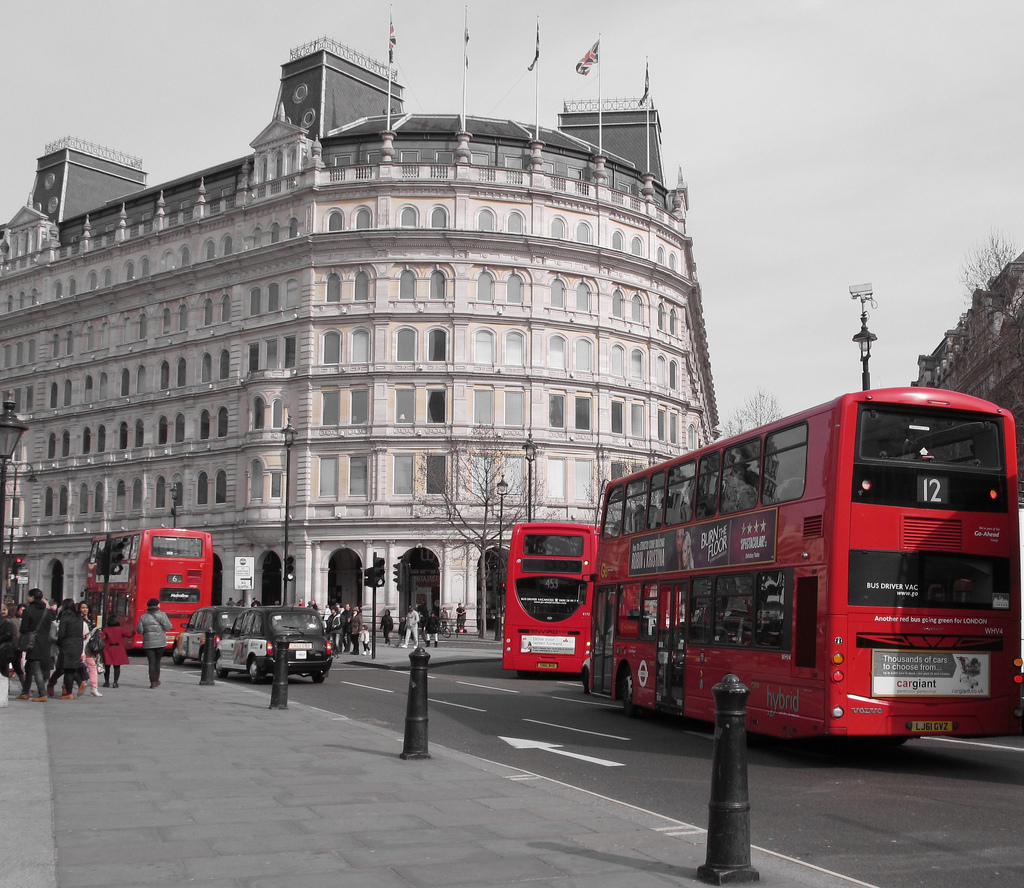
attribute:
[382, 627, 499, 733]
post — black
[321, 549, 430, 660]
light — black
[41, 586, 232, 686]
people — walking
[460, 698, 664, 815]
arrow — white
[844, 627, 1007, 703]
sign — white, gray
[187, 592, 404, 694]
car — black, white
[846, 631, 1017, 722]
sign — white, black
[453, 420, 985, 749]
bus — red, double decker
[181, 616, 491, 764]
pillars — black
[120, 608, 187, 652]
jacket — gray, puffy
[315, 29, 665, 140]
poles — attached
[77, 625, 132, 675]
coat — red, long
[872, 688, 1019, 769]
plate — yellow, black